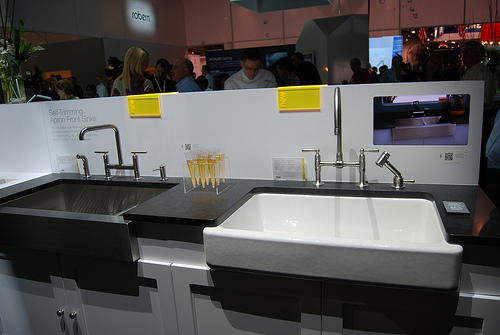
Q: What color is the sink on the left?
A: Black.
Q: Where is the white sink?
A: On the right.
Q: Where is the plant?
A: On the ledge.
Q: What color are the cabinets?
A: White.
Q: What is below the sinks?
A: Cabinets.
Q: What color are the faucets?
A: Silver.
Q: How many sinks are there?
A: 2.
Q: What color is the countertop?
A: Black.